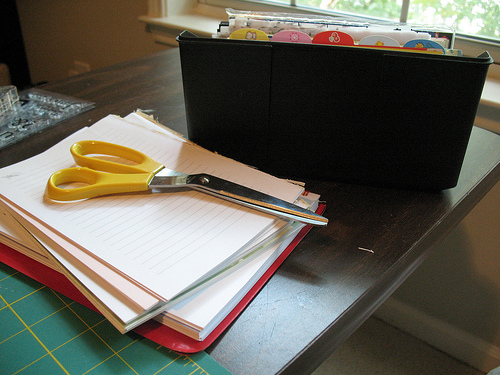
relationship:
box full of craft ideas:
[176, 21, 494, 193] [212, 3, 437, 28]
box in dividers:
[176, 21, 494, 193] [188, 12, 480, 60]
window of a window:
[142, 0, 500, 65] [137, 3, 497, 133]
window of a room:
[257, 0, 499, 42] [1, 1, 498, 373]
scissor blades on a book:
[43, 138, 329, 227] [0, 108, 323, 354]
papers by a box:
[212, 0, 452, 49] [176, 21, 494, 193]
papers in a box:
[212, 0, 452, 49] [176, 21, 494, 193]